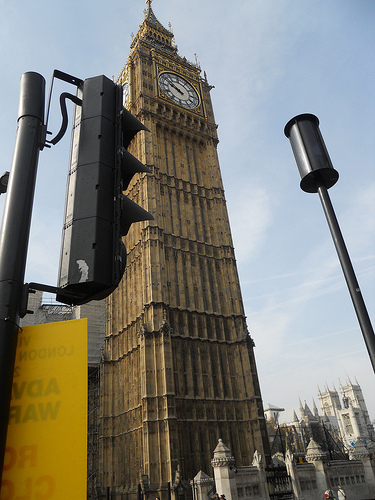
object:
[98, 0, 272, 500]
tower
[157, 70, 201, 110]
clock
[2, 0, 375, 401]
sky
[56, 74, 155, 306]
stop light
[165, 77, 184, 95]
hands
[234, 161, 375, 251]
cloud